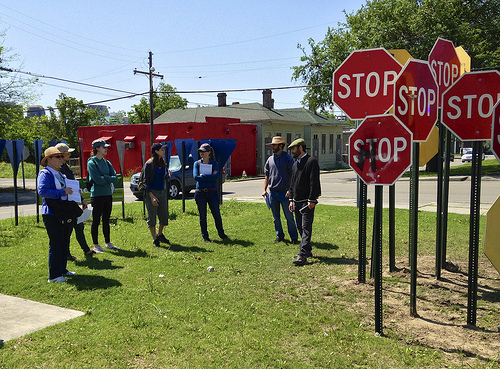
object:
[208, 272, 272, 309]
grass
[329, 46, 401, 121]
sign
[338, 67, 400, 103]
stop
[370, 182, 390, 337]
post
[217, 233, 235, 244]
feet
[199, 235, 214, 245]
shoes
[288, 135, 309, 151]
hat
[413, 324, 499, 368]
dirt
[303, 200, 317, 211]
hands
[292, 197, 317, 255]
pants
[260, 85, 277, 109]
chimney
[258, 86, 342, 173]
building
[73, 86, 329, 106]
line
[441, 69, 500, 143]
signs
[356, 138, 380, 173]
graffiti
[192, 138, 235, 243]
woman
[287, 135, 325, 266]
man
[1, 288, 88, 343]
block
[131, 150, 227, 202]
truck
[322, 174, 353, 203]
asphalt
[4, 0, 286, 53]
sky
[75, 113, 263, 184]
building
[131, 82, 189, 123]
tree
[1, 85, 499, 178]
back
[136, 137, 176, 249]
people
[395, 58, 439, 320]
signpost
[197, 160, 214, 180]
paper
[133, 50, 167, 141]
pole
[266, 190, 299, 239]
jean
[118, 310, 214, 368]
area